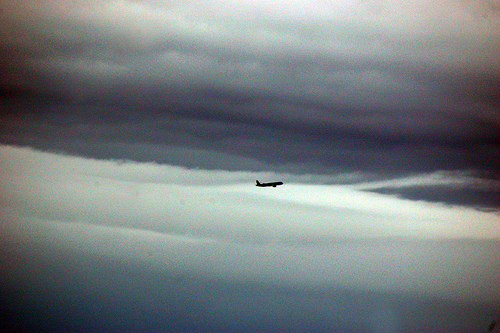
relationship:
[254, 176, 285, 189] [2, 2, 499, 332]
plane in sky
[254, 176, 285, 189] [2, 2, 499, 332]
plane near to sky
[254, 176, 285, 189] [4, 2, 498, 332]
plane near to clouds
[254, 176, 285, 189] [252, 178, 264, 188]
plane has back part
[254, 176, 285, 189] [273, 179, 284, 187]
plane has front part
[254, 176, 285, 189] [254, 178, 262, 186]
plane has wing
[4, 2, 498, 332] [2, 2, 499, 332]
clouds in sky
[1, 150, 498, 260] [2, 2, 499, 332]
cloud in sky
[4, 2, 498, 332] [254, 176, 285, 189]
clouds above plane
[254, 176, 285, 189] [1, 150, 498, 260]
plane in cloud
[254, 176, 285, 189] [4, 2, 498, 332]
plane flying into clouds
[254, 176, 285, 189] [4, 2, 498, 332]
plane among clouds